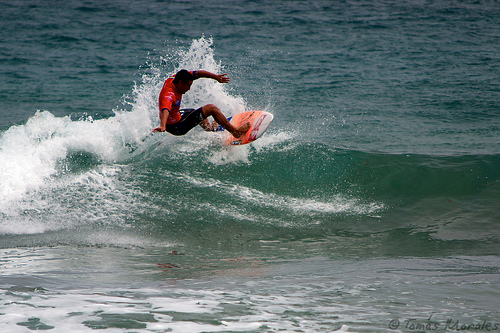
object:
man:
[151, 68, 251, 139]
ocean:
[1, 1, 499, 332]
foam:
[2, 108, 149, 234]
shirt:
[159, 70, 195, 125]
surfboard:
[217, 110, 275, 146]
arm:
[189, 70, 217, 80]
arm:
[157, 89, 175, 126]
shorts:
[166, 106, 209, 136]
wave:
[0, 31, 499, 256]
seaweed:
[153, 262, 185, 275]